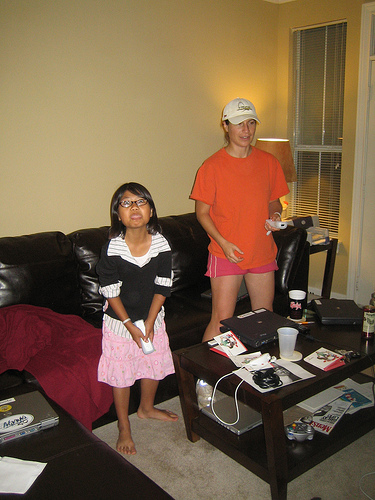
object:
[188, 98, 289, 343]
woman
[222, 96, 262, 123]
hat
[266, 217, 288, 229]
wii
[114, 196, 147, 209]
glasses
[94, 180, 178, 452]
girl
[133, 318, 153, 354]
controller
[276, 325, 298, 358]
cup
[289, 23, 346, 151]
blinds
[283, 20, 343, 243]
window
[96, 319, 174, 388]
skirt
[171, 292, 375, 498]
table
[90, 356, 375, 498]
carpet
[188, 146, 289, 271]
t-shirt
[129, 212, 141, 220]
tongue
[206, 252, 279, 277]
shorts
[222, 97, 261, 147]
head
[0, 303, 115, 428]
bedspread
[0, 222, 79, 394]
couch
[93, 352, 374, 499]
floor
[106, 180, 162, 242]
hair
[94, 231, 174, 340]
shirt